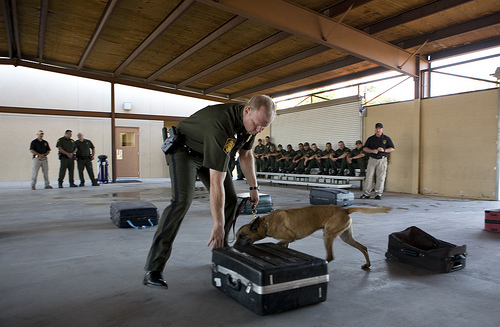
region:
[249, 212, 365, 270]
brown dog sniffing luggage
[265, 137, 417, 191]
line of officers sitting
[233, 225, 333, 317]
black hard case luggage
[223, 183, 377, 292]
brown dog with black nose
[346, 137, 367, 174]
police officer sitting on bench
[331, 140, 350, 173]
police officer sitting on bench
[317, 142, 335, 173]
police officer sitting on bench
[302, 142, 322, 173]
police officer sitting on bench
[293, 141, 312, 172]
police officer sitting on bench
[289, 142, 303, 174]
police officer sitting on bench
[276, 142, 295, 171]
police officer sitting on bench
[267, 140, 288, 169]
police officer sitting on bench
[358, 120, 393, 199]
person watching k9 demonstration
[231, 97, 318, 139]
man has short hair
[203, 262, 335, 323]
black and silver case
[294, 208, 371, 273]
dog has brown legs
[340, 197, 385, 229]
dog has brown tail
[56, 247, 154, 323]
concrete is dark grey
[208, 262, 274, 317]
black handle on case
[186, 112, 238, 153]
man has black shirt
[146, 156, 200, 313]
man has black pants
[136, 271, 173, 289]
man has black shoes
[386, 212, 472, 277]
Suitcase is open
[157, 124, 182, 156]
Gun of the officer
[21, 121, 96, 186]
Three men standing together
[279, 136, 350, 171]
Row of people sitting together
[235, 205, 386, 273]
Dog is sniffing a suitcase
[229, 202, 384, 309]
Dog is sniffing a black suitcase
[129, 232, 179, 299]
The officer is wearing a shoe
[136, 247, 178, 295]
The officer is wearing a black shoe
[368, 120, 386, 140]
The person has a hat on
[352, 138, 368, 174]
trainee looking at instructor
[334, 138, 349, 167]
trainee looking at instructor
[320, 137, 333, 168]
trainee looking at instructor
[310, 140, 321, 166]
trainee looking at instructor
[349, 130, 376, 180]
A person is sitting down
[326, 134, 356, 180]
A person is sitting down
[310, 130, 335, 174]
A person is sitting down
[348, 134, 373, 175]
A person is sitting down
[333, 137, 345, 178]
A person is sitting down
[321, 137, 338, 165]
A person is sitting down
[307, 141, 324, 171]
A person is sitting down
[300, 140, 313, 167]
A person is sitting down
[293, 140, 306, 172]
A person is sitting down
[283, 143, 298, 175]
A person is sitting down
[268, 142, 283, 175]
A person is sitting down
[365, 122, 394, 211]
A person is standing up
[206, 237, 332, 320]
black case on floor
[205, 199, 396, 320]
dog sniffing black case on floor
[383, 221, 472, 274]
black open suitcase on floor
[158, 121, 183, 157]
gun in holster on hip of police officer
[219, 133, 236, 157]
yellow badge on police officer's uniform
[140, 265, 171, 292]
black shoe on police officer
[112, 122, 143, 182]
peach colored door on wall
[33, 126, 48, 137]
white hat on man in tan pants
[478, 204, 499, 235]
edge of red suitcase on floor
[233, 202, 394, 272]
A brown dog sniffing.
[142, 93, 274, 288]
Police officer bent over with a dog